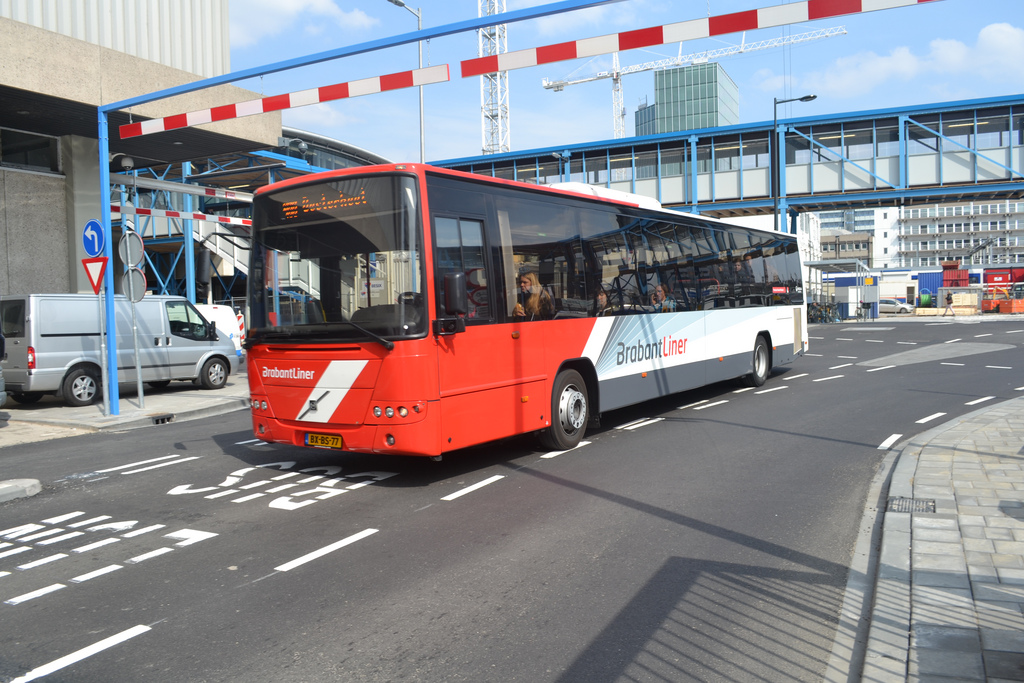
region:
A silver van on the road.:
[0, 289, 245, 406]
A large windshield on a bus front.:
[256, 182, 421, 335]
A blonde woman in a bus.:
[506, 267, 546, 316]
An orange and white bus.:
[247, 159, 810, 458]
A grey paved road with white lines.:
[0, 315, 1022, 680]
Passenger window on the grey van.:
[166, 299, 212, 339]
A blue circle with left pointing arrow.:
[79, 220, 106, 258]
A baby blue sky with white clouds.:
[226, 4, 1021, 153]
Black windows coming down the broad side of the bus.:
[425, 172, 806, 325]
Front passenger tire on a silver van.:
[194, 355, 229, 391]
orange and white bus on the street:
[247, 167, 804, 469]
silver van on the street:
[13, 282, 233, 399]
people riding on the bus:
[505, 240, 731, 313]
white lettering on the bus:
[259, 360, 321, 399]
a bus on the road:
[147, 110, 840, 632]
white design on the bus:
[216, 98, 976, 466]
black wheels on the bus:
[526, 344, 679, 475]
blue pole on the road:
[59, 82, 275, 490]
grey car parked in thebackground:
[11, 198, 303, 566]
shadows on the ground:
[572, 468, 866, 674]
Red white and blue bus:
[239, 147, 810, 471]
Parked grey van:
[4, 276, 239, 398]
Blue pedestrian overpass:
[304, 92, 1013, 210]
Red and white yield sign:
[81, 249, 111, 291]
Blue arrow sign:
[75, 217, 111, 259]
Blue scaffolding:
[111, 142, 315, 317]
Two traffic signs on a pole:
[81, 218, 114, 405]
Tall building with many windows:
[645, 62, 745, 155]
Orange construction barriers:
[980, 294, 1019, 313]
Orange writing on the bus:
[252, 170, 402, 221]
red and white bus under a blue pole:
[96, 3, 820, 463]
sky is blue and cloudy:
[232, 3, 1021, 165]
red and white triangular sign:
[81, 252, 114, 297]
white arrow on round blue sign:
[81, 218, 108, 260]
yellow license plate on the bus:
[245, 164, 809, 475]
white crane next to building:
[537, 19, 860, 141]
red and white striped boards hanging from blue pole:
[94, 8, 894, 420]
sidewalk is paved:
[855, 379, 1021, 678]